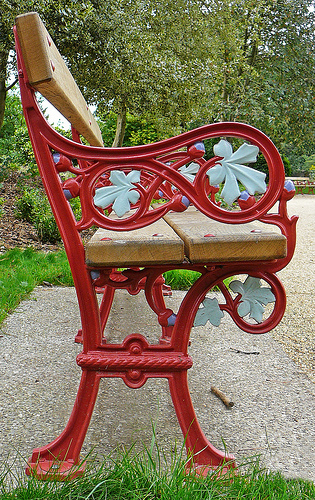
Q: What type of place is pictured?
A: It is a park.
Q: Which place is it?
A: It is a park.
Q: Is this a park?
A: Yes, it is a park.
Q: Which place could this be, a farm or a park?
A: It is a park.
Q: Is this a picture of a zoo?
A: No, the picture is showing a park.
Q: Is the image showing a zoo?
A: No, the picture is showing a park.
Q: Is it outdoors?
A: Yes, it is outdoors.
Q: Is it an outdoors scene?
A: Yes, it is outdoors.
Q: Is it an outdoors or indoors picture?
A: It is outdoors.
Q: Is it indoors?
A: No, it is outdoors.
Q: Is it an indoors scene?
A: No, it is outdoors.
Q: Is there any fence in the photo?
A: No, there are no fences.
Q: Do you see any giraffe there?
A: No, there are no giraffes.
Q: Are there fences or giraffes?
A: No, there are no giraffes or fences.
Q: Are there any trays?
A: No, there are no trays.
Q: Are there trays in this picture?
A: No, there are no trays.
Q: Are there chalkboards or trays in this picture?
A: No, there are no trays or chalkboards.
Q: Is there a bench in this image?
A: Yes, there is a bench.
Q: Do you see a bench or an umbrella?
A: Yes, there is a bench.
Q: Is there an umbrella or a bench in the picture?
A: Yes, there is a bench.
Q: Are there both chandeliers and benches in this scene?
A: No, there is a bench but no chandeliers.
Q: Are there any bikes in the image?
A: No, there are no bikes.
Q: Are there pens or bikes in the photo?
A: No, there are no bikes or pens.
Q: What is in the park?
A: The bench is in the park.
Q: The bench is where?
A: The bench is in the park.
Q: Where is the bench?
A: The bench is in the park.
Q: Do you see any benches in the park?
A: Yes, there is a bench in the park.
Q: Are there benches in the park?
A: Yes, there is a bench in the park.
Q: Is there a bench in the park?
A: Yes, there is a bench in the park.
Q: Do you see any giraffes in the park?
A: No, there is a bench in the park.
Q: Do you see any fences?
A: No, there are no fences.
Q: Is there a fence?
A: No, there are no fences.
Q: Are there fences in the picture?
A: No, there are no fences.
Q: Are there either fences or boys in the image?
A: No, there are no fences or boys.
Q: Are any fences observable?
A: No, there are no fences.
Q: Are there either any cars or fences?
A: No, there are no fences or cars.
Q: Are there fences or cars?
A: No, there are no fences or cars.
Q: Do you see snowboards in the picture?
A: No, there are no snowboards.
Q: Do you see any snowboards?
A: No, there are no snowboards.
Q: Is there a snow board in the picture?
A: No, there are no snowboards.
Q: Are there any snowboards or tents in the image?
A: No, there are no snowboards or tents.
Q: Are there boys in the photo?
A: No, there are no boys.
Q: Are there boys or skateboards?
A: No, there are no boys or skateboards.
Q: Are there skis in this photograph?
A: No, there are no skis.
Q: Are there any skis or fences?
A: No, there are no skis or fences.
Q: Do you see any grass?
A: Yes, there is grass.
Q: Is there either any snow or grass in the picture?
A: Yes, there is grass.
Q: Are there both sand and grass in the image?
A: No, there is grass but no sand.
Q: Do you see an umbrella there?
A: No, there are no umbrellas.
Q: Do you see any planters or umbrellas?
A: No, there are no umbrellas or planters.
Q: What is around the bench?
A: The grass is around the bench.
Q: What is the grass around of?
A: The grass is around the bench.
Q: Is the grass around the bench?
A: Yes, the grass is around the bench.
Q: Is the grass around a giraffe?
A: No, the grass is around the bench.